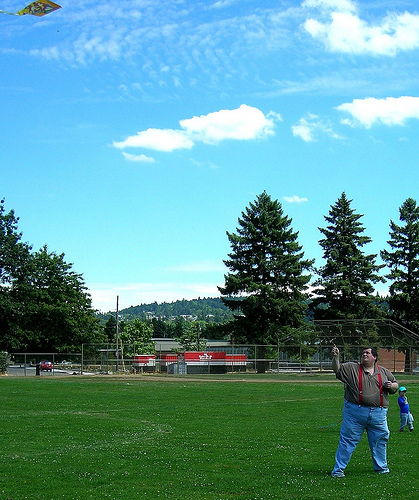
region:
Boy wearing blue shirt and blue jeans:
[394, 383, 416, 433]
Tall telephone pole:
[110, 289, 130, 369]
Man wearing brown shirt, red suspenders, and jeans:
[324, 341, 401, 483]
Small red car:
[35, 353, 57, 375]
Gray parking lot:
[11, 352, 86, 378]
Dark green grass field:
[2, 371, 413, 498]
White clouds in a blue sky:
[110, 101, 415, 162]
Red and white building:
[125, 348, 274, 386]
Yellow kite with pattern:
[2, 0, 67, 31]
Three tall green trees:
[223, 162, 418, 372]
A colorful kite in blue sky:
[2, 1, 73, 20]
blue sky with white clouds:
[5, 1, 418, 173]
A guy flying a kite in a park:
[0, 0, 398, 481]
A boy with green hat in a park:
[398, 385, 418, 434]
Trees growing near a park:
[1, 195, 416, 370]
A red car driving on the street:
[38, 359, 52, 373]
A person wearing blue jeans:
[327, 332, 392, 481]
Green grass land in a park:
[4, 371, 418, 499]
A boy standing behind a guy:
[320, 343, 415, 480]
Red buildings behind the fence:
[96, 336, 265, 373]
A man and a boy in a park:
[312, 323, 415, 478]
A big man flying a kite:
[310, 311, 396, 477]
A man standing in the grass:
[313, 334, 395, 492]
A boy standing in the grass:
[389, 376, 416, 441]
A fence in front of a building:
[129, 344, 321, 377]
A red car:
[32, 350, 59, 388]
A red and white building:
[127, 349, 257, 380]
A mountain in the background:
[125, 289, 234, 339]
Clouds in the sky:
[79, 56, 217, 173]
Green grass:
[59, 391, 217, 471]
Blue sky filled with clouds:
[70, 59, 284, 185]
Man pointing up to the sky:
[323, 329, 409, 493]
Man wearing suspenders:
[321, 316, 407, 485]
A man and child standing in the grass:
[325, 308, 416, 495]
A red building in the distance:
[120, 312, 269, 383]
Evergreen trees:
[210, 222, 417, 353]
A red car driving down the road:
[31, 347, 69, 378]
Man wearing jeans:
[320, 345, 403, 490]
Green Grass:
[61, 398, 258, 443]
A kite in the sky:
[2, 0, 101, 31]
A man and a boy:
[301, 329, 417, 435]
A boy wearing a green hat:
[395, 380, 414, 434]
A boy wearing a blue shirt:
[395, 385, 414, 436]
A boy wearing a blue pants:
[397, 379, 416, 438]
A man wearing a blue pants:
[325, 339, 391, 483]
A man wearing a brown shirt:
[314, 337, 399, 476]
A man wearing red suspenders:
[316, 331, 394, 478]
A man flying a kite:
[189, 216, 397, 472]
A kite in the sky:
[19, 4, 92, 45]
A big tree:
[216, 177, 307, 397]